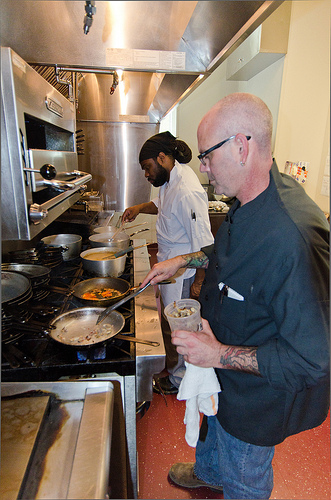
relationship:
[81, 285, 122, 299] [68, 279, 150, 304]
vegetables are in a skillet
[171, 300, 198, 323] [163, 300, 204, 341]
food in a container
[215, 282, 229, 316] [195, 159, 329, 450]
pen attached to shirt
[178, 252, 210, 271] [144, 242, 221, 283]
tattoo on arm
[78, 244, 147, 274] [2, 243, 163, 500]
pot on oven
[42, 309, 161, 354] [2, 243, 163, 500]
pan on oven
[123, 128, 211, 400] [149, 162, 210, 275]
man wearing a shirt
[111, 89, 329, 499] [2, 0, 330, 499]
man in kitchen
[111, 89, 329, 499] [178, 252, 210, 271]
man has a tattoo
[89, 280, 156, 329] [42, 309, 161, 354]
spatula over pan